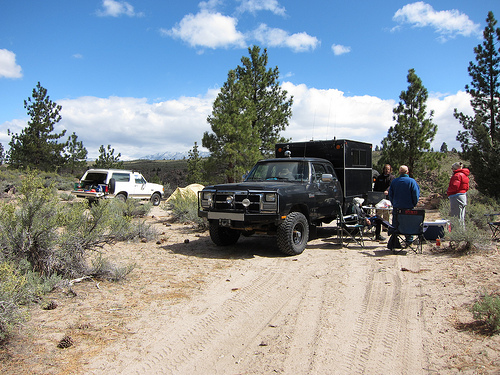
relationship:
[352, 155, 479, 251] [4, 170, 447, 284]
people at a camping site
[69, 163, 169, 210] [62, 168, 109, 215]
truck with camping equipment in back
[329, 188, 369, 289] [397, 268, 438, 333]
woman sitting in a chair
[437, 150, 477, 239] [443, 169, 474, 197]
woman in a red coats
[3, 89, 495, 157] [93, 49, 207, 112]
white clouds in sky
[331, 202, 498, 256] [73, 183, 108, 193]
camping chairs and stuff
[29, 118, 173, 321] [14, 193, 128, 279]
dried bare bushes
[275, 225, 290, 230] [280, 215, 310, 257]
tread black tread on a tire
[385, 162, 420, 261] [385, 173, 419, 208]
man wearing a blue coats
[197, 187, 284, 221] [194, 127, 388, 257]
rack on front of truck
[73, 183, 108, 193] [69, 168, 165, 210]
stuff on back of truck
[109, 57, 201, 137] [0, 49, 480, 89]
clouds in sky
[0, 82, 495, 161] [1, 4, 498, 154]
white clouds in sky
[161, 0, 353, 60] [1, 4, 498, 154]
clouds in sky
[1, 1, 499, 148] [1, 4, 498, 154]
clouds in sky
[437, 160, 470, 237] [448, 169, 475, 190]
woman wearing coats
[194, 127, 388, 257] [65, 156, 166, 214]
truck with stuff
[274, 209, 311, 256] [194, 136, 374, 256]
wheel of truck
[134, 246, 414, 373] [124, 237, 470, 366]
tracks in sand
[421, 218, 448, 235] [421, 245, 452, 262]
cooler on ground